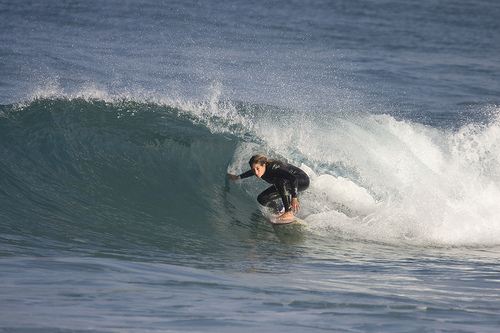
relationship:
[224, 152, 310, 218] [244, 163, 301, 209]
surfer wearing a wetsuit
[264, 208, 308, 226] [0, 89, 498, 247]
surfboard on wave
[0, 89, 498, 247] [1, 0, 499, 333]
wave breaking in ocean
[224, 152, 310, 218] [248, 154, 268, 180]
surfer has a head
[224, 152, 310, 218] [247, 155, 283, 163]
surfer has hair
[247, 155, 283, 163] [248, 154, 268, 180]
hair on head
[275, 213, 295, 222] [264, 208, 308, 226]
foot on surfboard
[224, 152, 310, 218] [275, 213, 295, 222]
surfer has a foot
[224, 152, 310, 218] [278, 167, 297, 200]
surfer has arm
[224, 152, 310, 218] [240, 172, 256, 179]
surfer has arm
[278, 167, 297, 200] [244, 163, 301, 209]
arm in wetsuit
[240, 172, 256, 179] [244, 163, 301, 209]
arm in wetsuit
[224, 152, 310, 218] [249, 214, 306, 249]
surfer has a reflection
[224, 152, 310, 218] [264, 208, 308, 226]
surfer riding surfboard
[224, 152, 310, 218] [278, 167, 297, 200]
surfer has an arm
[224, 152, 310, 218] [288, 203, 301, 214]
surfer has a hand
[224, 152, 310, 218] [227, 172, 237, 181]
surfer has a hand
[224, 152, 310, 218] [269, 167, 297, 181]
surfer has a torso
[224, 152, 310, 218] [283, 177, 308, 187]
surfer has a thigh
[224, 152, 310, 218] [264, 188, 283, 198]
surfer has a thigh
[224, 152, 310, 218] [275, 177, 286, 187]
surfer has a knee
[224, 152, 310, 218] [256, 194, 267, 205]
surfer has a knee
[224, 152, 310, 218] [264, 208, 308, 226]
surfer on surfboard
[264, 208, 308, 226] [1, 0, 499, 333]
surfboard in ocean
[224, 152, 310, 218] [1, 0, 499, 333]
surfer touching ocean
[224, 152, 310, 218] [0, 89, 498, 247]
surfer touching wave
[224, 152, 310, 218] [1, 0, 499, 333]
surfer in ocean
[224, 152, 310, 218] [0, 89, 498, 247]
surfer surfing a wave